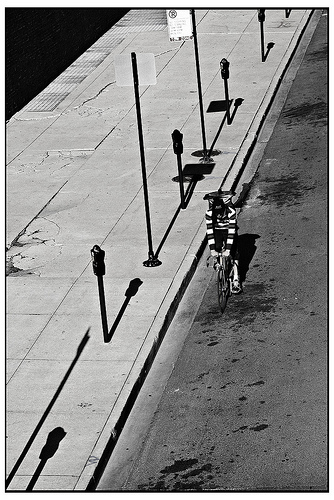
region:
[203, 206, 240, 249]
striped shirt on cyclist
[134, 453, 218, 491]
oil stains on pavement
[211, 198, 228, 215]
baseball cap on cyclist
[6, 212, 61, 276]
busted up sidewalk area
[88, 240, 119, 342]
parking meter on sidewalk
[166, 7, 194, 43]
no parking sign on pole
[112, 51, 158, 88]
reverse side of traffic sign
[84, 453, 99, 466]
graffiti painted on curb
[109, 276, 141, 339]
shadow from parking meter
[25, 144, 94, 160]
raised piece of sidewalk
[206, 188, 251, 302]
a guy riding a bike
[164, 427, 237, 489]
black stains on a street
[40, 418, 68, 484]
the shadow of a street sign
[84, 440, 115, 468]
the curb of a street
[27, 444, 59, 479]
a crack in the sidewalk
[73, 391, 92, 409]
a smudge on the sidewalk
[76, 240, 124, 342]
a small black parking meter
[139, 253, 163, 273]
the base of a street lamp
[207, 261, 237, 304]
the front wheel of a tire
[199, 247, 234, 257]
the hands of a man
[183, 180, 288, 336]
this is a person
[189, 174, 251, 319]
a person riding a bike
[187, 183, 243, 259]
person wearing a striped shirt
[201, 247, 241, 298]
this is a bike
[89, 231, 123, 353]
this is a parking meter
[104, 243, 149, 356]
shadow of the parking meter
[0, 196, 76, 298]
cracked hole in sidewalk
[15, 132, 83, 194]
hair line cracks in sidewalk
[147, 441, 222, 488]
black signs on street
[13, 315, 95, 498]
shadow of a pole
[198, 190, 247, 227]
face of the girl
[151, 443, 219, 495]
marks in the raod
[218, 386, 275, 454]
black marks in the road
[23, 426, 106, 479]
shadow falling on the road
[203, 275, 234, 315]
tire of the bicycle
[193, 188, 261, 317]
a girl sitting in cycle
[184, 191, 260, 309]
a girl doing cycling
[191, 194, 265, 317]
a girl cycling in road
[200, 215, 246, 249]
girl wearing a t shirt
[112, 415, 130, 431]
side of the road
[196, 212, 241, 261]
the shirt is stripes